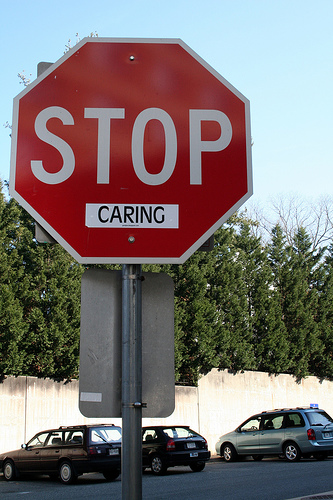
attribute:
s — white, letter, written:
[33, 112, 74, 184]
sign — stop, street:
[14, 26, 251, 265]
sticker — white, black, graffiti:
[89, 203, 174, 227]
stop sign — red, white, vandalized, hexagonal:
[17, 41, 240, 258]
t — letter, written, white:
[81, 105, 117, 186]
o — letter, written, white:
[128, 101, 178, 187]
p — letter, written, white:
[185, 103, 232, 197]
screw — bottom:
[126, 237, 134, 246]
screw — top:
[125, 51, 137, 67]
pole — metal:
[115, 267, 137, 389]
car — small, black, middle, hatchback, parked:
[141, 410, 223, 477]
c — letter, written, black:
[97, 203, 112, 226]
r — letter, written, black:
[124, 205, 134, 229]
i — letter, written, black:
[135, 205, 140, 226]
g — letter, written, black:
[154, 201, 169, 225]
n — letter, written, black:
[143, 203, 155, 226]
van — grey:
[207, 416, 329, 453]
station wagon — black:
[0, 421, 125, 494]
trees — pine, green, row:
[3, 192, 319, 367]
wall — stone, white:
[7, 358, 331, 452]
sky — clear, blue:
[4, 7, 324, 213]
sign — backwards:
[91, 266, 160, 368]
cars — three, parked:
[48, 419, 329, 471]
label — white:
[75, 393, 110, 410]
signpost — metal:
[121, 275, 137, 453]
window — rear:
[87, 430, 126, 444]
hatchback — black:
[16, 423, 118, 475]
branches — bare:
[315, 212, 333, 242]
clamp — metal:
[114, 271, 153, 283]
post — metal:
[121, 262, 144, 371]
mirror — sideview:
[162, 432, 174, 437]